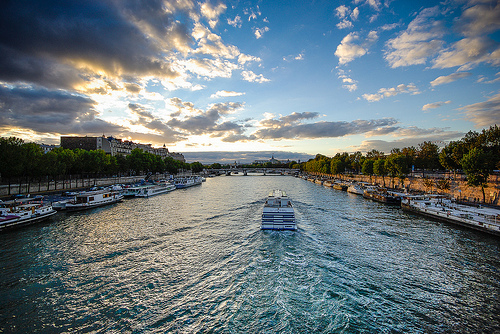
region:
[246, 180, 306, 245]
The boat in the center of the waer.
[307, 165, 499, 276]
The boats parked on the right side.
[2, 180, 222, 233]
The boats on the left side.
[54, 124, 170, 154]
The buildings on the left side.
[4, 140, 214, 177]
The trees lined up along the left.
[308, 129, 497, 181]
The trees lined up along the right.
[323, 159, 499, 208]
The sand on the ground on the right.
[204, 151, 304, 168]
The trees in the far distance.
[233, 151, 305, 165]
The buildings in the far distance.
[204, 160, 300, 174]
The bridge in the far distance.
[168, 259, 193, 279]
Small part of the blue water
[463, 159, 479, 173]
Medium section of a green tree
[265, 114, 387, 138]
Large cloud in the sky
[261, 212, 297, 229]
Back of a blue and white boat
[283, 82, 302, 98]
Small part of the blue sky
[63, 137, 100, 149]
One of the buildings in the distance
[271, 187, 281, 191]
Front section of the boat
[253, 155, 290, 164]
Building in the far distance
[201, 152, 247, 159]
Hills in the background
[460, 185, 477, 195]
Small patch of dirt next to the boats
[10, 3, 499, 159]
White clouds in the sky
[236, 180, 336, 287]
A boat traveling in the middle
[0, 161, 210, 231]
boats parked along the left bank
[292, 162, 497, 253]
boats parked along the right bank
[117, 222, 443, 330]
small waves in the water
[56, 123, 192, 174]
a large long building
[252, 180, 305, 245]
a white boat traveling in water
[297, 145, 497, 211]
many trees along right bank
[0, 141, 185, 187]
many trees along left bank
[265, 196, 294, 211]
Two people sit on back of traveling boat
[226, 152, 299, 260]
a boat in the water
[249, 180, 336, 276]
a big boat in the water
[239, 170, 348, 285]
a boat driving in the water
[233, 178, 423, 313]
a big boat driving down the water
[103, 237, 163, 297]
a body of water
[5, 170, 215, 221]
boats parked on the water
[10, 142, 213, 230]
boats parked along the sidwalk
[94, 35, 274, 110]
a sky with clouds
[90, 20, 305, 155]
clouds in the sky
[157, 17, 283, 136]
clouds in a blue sky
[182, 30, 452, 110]
this is the sky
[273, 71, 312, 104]
the sky is blue in color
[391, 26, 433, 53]
these are the clouds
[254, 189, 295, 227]
this is a ship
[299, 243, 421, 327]
this is a water body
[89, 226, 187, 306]
the water is calm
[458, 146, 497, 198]
this is a tree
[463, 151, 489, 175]
the leaves are green in color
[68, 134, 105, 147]
this is a building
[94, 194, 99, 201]
the ship is white in color